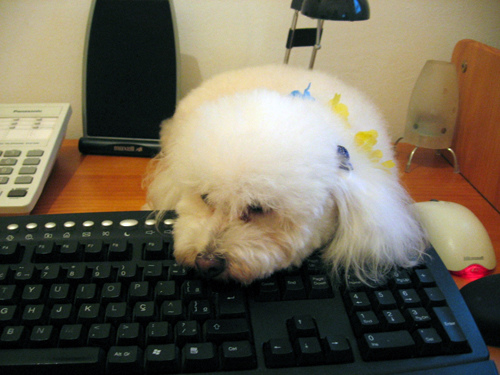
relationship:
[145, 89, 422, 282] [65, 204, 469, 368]
head on keyboard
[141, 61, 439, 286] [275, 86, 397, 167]
dog wearing collar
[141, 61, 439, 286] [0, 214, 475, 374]
dog on keys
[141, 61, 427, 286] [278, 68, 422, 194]
dog has flowers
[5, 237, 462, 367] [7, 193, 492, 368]
buttons on keyboard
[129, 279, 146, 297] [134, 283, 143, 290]
key with letter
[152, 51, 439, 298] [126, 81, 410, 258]
fur on dog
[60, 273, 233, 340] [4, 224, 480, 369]
buttons on keyboard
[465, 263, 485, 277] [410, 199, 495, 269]
light under mouse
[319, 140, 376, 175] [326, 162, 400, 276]
bow on ear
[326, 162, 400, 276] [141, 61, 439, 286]
ear on dog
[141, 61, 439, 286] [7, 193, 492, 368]
dog on keyboard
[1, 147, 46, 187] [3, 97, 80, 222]
grey buttons on telephone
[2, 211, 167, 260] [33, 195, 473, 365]
buttons on keyboard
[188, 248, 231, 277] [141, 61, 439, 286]
nose on dog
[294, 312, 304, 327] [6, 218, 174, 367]
arrow on keyboard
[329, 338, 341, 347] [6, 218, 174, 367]
arrow on keyboard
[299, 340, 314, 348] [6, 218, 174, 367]
arrow on keyboard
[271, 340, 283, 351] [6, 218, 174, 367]
arrow on keyboard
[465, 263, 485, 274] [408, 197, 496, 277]
light under mouse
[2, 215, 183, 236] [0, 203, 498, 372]
function keys on keyboard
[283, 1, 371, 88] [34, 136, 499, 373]
lamp on brown table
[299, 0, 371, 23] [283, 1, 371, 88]
hood on lamp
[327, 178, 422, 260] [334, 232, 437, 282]
fluffy fur on number pad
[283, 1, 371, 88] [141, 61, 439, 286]
lamp behind dog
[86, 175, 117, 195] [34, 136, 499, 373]
part of brown table